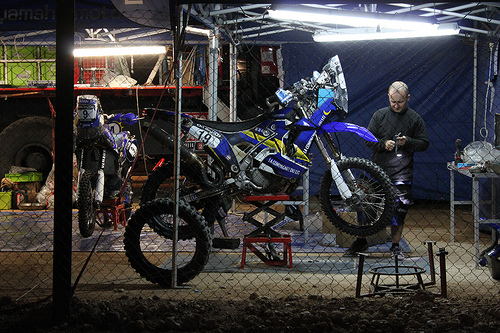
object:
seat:
[193, 110, 280, 132]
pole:
[52, 2, 72, 300]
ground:
[0, 200, 500, 280]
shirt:
[365, 105, 429, 182]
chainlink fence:
[0, 0, 499, 309]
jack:
[242, 195, 293, 269]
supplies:
[77, 56, 154, 87]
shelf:
[0, 85, 203, 92]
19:
[198, 131, 212, 144]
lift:
[241, 204, 293, 269]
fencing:
[4, 10, 499, 322]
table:
[447, 162, 497, 267]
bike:
[139, 56, 397, 241]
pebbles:
[300, 311, 314, 317]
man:
[341, 81, 430, 261]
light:
[394, 132, 404, 157]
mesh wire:
[294, 236, 343, 282]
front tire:
[319, 157, 397, 237]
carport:
[2, 0, 499, 302]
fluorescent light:
[268, 2, 460, 42]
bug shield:
[308, 54, 348, 113]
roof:
[0, 19, 500, 45]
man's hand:
[397, 136, 406, 146]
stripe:
[243, 131, 310, 163]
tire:
[124, 197, 213, 285]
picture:
[15, 19, 469, 312]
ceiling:
[196, 0, 500, 42]